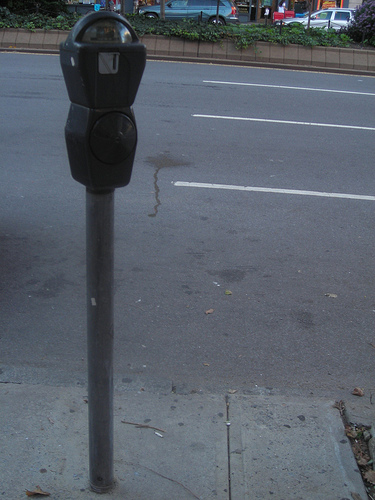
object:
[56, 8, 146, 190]
parking meter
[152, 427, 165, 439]
cigarette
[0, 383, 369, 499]
sidewalk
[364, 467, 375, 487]
leaves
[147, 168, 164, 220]
crack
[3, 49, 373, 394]
road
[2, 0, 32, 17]
bushes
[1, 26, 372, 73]
planter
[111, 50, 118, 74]
coin slot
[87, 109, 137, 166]
lid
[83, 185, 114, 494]
post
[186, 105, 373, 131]
stripes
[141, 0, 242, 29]
cars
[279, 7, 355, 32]
car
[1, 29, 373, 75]
wall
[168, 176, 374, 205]
line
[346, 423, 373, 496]
dirt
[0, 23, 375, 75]
median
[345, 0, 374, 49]
bush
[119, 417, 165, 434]
stick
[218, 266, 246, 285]
spill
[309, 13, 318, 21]
mirror